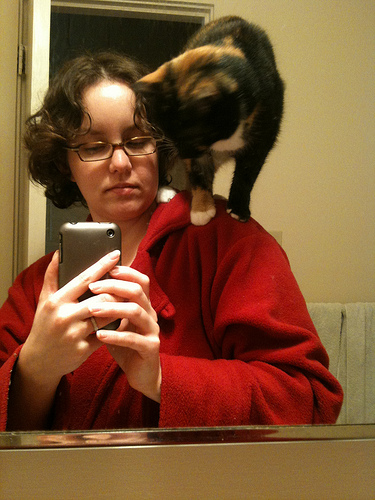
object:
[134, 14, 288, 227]
cat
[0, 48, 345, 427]
woman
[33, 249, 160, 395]
hands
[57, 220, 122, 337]
smartphone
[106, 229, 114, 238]
camera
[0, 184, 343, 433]
robe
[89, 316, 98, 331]
ring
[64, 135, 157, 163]
glasses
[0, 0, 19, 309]
door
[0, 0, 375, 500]
bathroom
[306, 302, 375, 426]
towel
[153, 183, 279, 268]
shoulder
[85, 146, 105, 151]
eyes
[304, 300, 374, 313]
rack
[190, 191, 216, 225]
paw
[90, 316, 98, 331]
finger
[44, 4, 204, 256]
doorway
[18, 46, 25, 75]
hinge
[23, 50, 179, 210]
hair